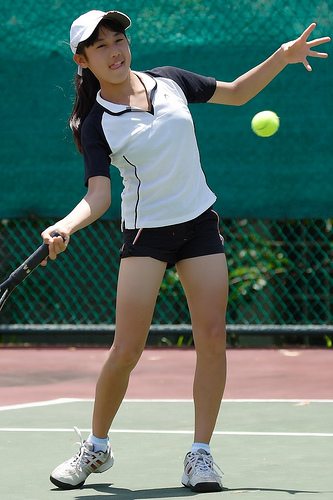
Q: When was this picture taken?
A: Daytime.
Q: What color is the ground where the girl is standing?
A: Green.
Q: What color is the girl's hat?
A: White.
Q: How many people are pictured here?
A: One.